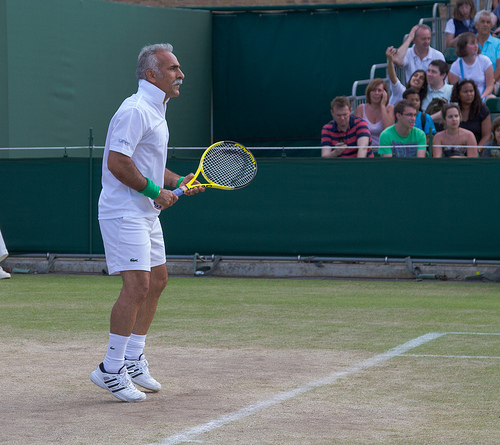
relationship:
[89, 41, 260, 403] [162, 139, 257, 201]
man holding racket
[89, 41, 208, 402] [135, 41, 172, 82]
man with hair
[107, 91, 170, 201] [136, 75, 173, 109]
shirt with collar